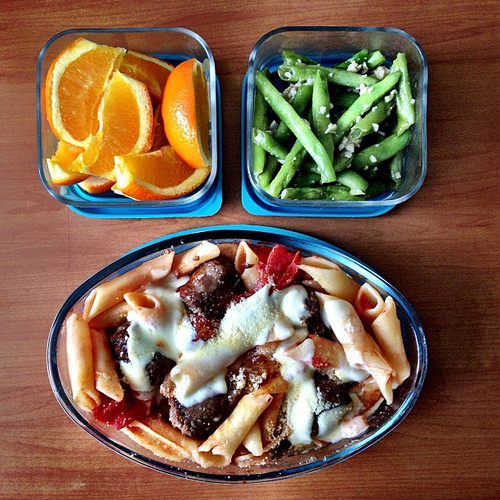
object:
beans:
[252, 48, 414, 201]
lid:
[241, 48, 397, 217]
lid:
[65, 50, 224, 219]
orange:
[45, 37, 212, 201]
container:
[35, 26, 219, 208]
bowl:
[45, 224, 427, 485]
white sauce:
[120, 281, 352, 428]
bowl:
[246, 25, 428, 209]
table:
[0, 0, 499, 500]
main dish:
[67, 240, 410, 466]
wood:
[1, 0, 498, 500]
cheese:
[129, 285, 303, 374]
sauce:
[118, 258, 375, 442]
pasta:
[66, 240, 409, 469]